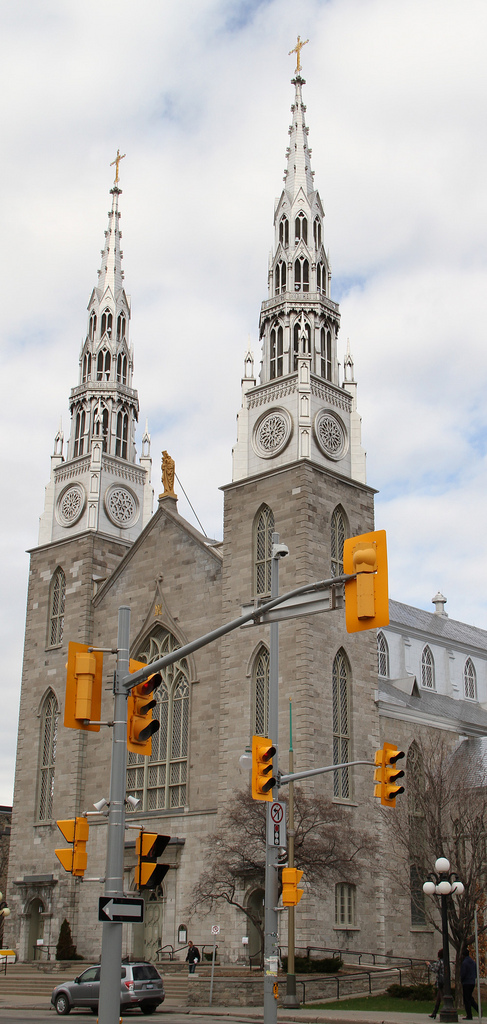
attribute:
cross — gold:
[108, 146, 124, 180]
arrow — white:
[100, 896, 142, 921]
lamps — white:
[421, 855, 463, 896]